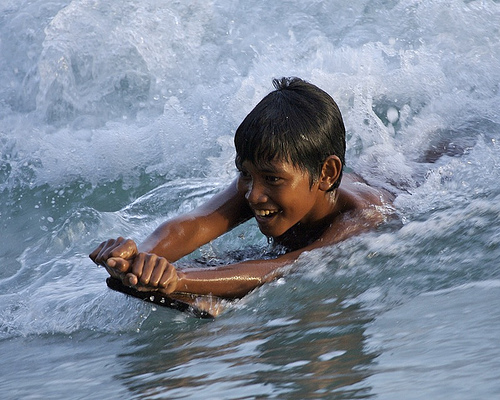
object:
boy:
[88, 77, 394, 295]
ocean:
[0, 0, 500, 400]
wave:
[0, 169, 231, 266]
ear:
[321, 155, 343, 193]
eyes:
[265, 172, 288, 187]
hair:
[233, 78, 345, 193]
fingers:
[157, 263, 175, 291]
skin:
[331, 179, 381, 232]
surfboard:
[105, 274, 216, 320]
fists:
[125, 252, 176, 295]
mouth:
[247, 206, 285, 219]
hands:
[88, 236, 139, 274]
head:
[233, 76, 345, 237]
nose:
[243, 178, 269, 206]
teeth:
[256, 210, 267, 220]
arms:
[178, 218, 368, 294]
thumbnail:
[128, 274, 139, 284]